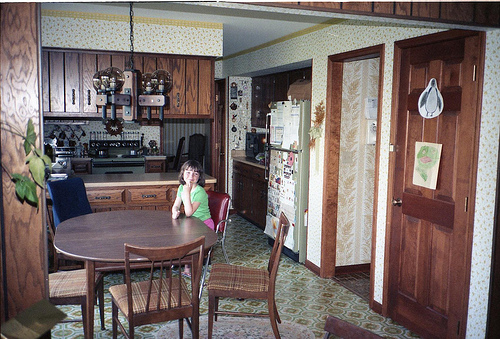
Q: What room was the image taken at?
A: It was taken at the kitchen.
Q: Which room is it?
A: It is a kitchen.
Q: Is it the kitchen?
A: Yes, it is the kitchen.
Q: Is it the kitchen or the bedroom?
A: It is the kitchen.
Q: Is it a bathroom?
A: No, it is a kitchen.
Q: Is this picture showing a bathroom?
A: No, the picture is showing a kitchen.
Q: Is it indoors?
A: Yes, it is indoors.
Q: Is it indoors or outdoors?
A: It is indoors.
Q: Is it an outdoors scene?
A: No, it is indoors.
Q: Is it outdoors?
A: No, it is indoors.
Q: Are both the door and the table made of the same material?
A: Yes, both the door and the table are made of wood.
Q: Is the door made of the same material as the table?
A: Yes, both the door and the table are made of wood.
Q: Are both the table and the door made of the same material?
A: Yes, both the table and the door are made of wood.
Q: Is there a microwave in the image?
A: Yes, there is a microwave.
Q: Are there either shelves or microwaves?
A: Yes, there is a microwave.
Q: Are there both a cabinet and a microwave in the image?
A: Yes, there are both a microwave and a cabinet.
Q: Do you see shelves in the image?
A: No, there are no shelves.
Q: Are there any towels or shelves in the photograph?
A: No, there are no shelves or towels.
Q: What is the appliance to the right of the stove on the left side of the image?
A: The appliance is a microwave.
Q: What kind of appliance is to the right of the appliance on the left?
A: The appliance is a microwave.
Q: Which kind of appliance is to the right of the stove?
A: The appliance is a microwave.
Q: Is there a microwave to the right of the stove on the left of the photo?
A: Yes, there is a microwave to the right of the stove.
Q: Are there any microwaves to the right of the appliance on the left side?
A: Yes, there is a microwave to the right of the stove.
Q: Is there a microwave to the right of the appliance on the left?
A: Yes, there is a microwave to the right of the stove.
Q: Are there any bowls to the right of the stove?
A: No, there is a microwave to the right of the stove.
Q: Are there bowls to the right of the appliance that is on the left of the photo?
A: No, there is a microwave to the right of the stove.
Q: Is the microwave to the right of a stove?
A: Yes, the microwave is to the right of a stove.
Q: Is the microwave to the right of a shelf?
A: No, the microwave is to the right of a stove.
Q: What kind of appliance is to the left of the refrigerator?
A: The appliance is a microwave.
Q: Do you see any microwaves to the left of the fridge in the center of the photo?
A: Yes, there is a microwave to the left of the fridge.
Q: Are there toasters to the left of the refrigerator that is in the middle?
A: No, there is a microwave to the left of the fridge.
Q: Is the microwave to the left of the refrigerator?
A: Yes, the microwave is to the left of the refrigerator.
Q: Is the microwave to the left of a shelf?
A: No, the microwave is to the left of the refrigerator.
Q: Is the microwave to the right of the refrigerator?
A: No, the microwave is to the left of the refrigerator.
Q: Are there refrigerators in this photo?
A: Yes, there is a refrigerator.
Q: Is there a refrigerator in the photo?
A: Yes, there is a refrigerator.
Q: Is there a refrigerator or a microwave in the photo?
A: Yes, there is a refrigerator.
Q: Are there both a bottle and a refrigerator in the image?
A: No, there is a refrigerator but no bottles.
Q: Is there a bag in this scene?
A: No, there are no bags.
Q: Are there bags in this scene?
A: No, there are no bags.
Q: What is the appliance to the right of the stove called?
A: The appliance is a refrigerator.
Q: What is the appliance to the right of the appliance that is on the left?
A: The appliance is a refrigerator.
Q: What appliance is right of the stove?
A: The appliance is a refrigerator.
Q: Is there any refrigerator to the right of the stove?
A: Yes, there is a refrigerator to the right of the stove.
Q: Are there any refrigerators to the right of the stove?
A: Yes, there is a refrigerator to the right of the stove.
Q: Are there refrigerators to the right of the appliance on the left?
A: Yes, there is a refrigerator to the right of the stove.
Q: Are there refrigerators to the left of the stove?
A: No, the refrigerator is to the right of the stove.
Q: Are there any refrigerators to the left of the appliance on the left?
A: No, the refrigerator is to the right of the stove.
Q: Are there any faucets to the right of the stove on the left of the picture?
A: No, there is a refrigerator to the right of the stove.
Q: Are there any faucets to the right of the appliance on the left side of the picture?
A: No, there is a refrigerator to the right of the stove.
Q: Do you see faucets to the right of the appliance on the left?
A: No, there is a refrigerator to the right of the stove.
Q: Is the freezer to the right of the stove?
A: Yes, the freezer is to the right of the stove.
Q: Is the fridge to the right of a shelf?
A: No, the fridge is to the right of the stove.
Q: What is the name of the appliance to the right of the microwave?
A: The appliance is a refrigerator.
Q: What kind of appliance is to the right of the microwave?
A: The appliance is a refrigerator.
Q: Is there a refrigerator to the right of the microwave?
A: Yes, there is a refrigerator to the right of the microwave.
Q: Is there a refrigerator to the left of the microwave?
A: No, the refrigerator is to the right of the microwave.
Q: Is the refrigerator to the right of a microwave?
A: Yes, the refrigerator is to the right of a microwave.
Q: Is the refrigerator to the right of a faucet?
A: No, the refrigerator is to the right of a microwave.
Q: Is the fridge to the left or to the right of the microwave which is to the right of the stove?
A: The fridge is to the right of the microwave.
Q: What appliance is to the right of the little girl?
A: The appliance is a refrigerator.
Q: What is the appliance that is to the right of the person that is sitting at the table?
A: The appliance is a refrigerator.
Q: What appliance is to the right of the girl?
A: The appliance is a refrigerator.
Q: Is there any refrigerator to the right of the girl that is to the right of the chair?
A: Yes, there is a refrigerator to the right of the girl.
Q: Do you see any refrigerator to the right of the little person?
A: Yes, there is a refrigerator to the right of the girl.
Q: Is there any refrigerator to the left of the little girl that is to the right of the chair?
A: No, the refrigerator is to the right of the girl.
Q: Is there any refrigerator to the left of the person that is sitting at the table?
A: No, the refrigerator is to the right of the girl.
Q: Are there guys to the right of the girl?
A: No, there is a refrigerator to the right of the girl.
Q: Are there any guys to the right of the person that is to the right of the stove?
A: No, there is a refrigerator to the right of the girl.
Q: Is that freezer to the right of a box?
A: No, the freezer is to the right of a girl.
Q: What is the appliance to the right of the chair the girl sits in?
A: The appliance is a refrigerator.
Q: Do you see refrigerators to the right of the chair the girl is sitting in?
A: Yes, there is a refrigerator to the right of the chair.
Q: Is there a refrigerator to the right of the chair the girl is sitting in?
A: Yes, there is a refrigerator to the right of the chair.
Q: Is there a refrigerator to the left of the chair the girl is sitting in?
A: No, the refrigerator is to the right of the chair.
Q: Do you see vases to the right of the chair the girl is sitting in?
A: No, there is a refrigerator to the right of the chair.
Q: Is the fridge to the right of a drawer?
A: No, the fridge is to the right of the chair.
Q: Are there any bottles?
A: No, there are no bottles.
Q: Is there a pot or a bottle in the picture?
A: No, there are no bottles or pots.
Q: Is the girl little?
A: Yes, the girl is little.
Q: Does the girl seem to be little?
A: Yes, the girl is little.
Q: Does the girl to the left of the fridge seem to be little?
A: Yes, the girl is little.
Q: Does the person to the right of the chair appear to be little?
A: Yes, the girl is little.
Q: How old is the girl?
A: The girl is little.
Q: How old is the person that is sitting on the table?
A: The girl is little.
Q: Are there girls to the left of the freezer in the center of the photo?
A: Yes, there is a girl to the left of the refrigerator.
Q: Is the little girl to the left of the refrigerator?
A: Yes, the girl is to the left of the refrigerator.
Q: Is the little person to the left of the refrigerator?
A: Yes, the girl is to the left of the refrigerator.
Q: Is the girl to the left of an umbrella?
A: No, the girl is to the left of the refrigerator.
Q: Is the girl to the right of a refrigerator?
A: No, the girl is to the left of a refrigerator.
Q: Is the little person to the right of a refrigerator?
A: No, the girl is to the left of a refrigerator.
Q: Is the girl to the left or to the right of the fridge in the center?
A: The girl is to the left of the freezer.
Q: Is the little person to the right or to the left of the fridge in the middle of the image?
A: The girl is to the left of the freezer.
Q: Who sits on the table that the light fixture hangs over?
A: The girl sits on the table.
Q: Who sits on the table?
A: The girl sits on the table.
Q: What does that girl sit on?
A: The girl sits on the table.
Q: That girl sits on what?
A: The girl sits on the table.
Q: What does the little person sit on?
A: The girl sits on the table.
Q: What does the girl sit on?
A: The girl sits on the table.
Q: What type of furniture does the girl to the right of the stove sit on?
A: The girl sits on the table.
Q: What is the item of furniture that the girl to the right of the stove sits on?
A: The piece of furniture is a table.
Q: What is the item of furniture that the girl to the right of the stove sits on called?
A: The piece of furniture is a table.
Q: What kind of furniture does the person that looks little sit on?
A: The girl sits on the table.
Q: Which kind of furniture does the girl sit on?
A: The girl sits on the table.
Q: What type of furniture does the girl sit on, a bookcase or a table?
A: The girl sits on a table.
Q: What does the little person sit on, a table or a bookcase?
A: The girl sits on a table.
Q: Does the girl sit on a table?
A: Yes, the girl sits on a table.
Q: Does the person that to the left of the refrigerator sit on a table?
A: Yes, the girl sits on a table.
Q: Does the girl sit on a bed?
A: No, the girl sits on a table.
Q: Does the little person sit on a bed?
A: No, the girl sits on a table.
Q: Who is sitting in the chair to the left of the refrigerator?
A: The girl is sitting in the chair.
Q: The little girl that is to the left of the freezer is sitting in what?
A: The girl is sitting in the chair.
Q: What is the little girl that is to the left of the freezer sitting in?
A: The girl is sitting in the chair.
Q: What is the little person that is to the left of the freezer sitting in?
A: The girl is sitting in the chair.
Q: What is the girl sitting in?
A: The girl is sitting in the chair.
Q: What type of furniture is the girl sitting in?
A: The girl is sitting in the chair.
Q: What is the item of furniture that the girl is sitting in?
A: The piece of furniture is a chair.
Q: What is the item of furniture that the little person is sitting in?
A: The piece of furniture is a chair.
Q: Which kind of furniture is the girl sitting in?
A: The girl is sitting in the chair.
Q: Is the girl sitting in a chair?
A: Yes, the girl is sitting in a chair.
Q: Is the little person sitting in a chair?
A: Yes, the girl is sitting in a chair.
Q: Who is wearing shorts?
A: The girl is wearing shorts.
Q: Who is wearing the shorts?
A: The girl is wearing shorts.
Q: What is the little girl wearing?
A: The girl is wearing shorts.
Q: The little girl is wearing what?
A: The girl is wearing shorts.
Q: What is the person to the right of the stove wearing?
A: The girl is wearing shorts.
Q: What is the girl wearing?
A: The girl is wearing shorts.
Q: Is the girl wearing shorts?
A: Yes, the girl is wearing shorts.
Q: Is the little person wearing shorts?
A: Yes, the girl is wearing shorts.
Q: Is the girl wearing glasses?
A: No, the girl is wearing shorts.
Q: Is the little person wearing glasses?
A: No, the girl is wearing shorts.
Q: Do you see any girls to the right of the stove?
A: Yes, there is a girl to the right of the stove.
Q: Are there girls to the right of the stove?
A: Yes, there is a girl to the right of the stove.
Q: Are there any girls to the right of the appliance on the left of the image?
A: Yes, there is a girl to the right of the stove.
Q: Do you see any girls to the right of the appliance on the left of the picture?
A: Yes, there is a girl to the right of the stove.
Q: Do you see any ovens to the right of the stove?
A: No, there is a girl to the right of the stove.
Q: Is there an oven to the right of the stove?
A: No, there is a girl to the right of the stove.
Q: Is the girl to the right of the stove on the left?
A: Yes, the girl is to the right of the stove.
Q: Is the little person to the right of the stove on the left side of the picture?
A: Yes, the girl is to the right of the stove.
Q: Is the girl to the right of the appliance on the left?
A: Yes, the girl is to the right of the stove.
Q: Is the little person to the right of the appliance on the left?
A: Yes, the girl is to the right of the stove.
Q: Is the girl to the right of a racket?
A: No, the girl is to the right of the stove.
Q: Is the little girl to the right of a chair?
A: Yes, the girl is to the right of a chair.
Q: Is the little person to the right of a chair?
A: Yes, the girl is to the right of a chair.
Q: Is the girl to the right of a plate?
A: No, the girl is to the right of a chair.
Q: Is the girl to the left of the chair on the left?
A: No, the girl is to the right of the chair.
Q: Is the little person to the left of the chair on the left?
A: No, the girl is to the right of the chair.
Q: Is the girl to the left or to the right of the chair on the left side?
A: The girl is to the right of the chair.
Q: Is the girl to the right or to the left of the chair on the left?
A: The girl is to the right of the chair.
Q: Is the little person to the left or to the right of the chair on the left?
A: The girl is to the right of the chair.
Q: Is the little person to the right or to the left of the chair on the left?
A: The girl is to the right of the chair.